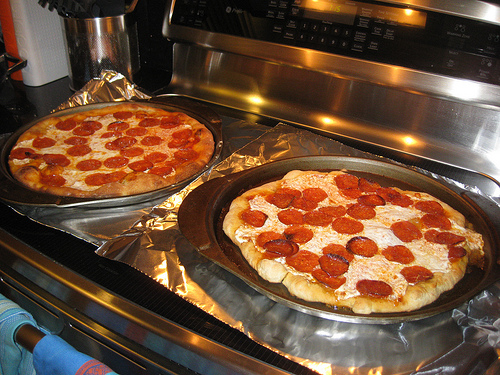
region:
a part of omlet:
[60, 83, 259, 276]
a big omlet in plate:
[222, 164, 464, 320]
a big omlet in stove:
[245, 158, 437, 328]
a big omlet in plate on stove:
[212, 173, 469, 334]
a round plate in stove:
[174, 204, 228, 264]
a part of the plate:
[159, 185, 219, 255]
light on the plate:
[310, 303, 366, 350]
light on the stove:
[278, 293, 365, 360]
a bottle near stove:
[13, 305, 92, 369]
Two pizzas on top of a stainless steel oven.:
[0, 1, 498, 374]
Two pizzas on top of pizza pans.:
[5, 99, 499, 321]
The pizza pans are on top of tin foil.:
[2, 69, 499, 374]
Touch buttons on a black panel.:
[171, 0, 498, 84]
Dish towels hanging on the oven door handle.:
[0, 281, 120, 373]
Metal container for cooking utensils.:
[66, 3, 136, 95]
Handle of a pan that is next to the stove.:
[0, 49, 28, 80]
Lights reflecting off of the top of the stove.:
[246, 0, 423, 150]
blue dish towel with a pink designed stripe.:
[31, 333, 131, 374]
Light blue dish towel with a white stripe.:
[1, 297, 52, 374]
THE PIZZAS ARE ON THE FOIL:
[10, 91, 496, 364]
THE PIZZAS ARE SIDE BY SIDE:
[0, 85, 496, 360]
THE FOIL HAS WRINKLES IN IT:
[88, 120, 497, 373]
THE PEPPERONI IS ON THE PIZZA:
[220, 157, 496, 342]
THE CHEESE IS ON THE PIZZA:
[217, 152, 477, 337]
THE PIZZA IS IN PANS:
[0, 92, 496, 337]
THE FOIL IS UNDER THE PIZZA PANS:
[0, 62, 496, 372]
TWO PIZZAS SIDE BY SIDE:
[0, 65, 497, 365]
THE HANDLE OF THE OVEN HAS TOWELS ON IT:
[0, 292, 135, 372]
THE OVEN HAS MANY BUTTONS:
[249, 0, 423, 73]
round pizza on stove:
[21, 110, 209, 188]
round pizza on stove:
[232, 188, 482, 322]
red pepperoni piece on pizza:
[319, 249, 349, 280]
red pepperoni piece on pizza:
[288, 246, 328, 280]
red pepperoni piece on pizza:
[266, 233, 294, 260]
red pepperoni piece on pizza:
[235, 203, 266, 226]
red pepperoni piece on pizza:
[275, 209, 308, 224]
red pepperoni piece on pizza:
[273, 191, 295, 204]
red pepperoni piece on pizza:
[109, 152, 131, 169]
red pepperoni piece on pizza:
[78, 119, 100, 132]